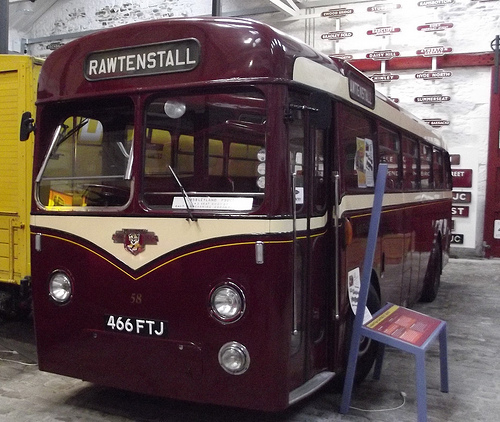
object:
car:
[18, 15, 446, 415]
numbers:
[102, 312, 170, 339]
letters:
[85, 47, 198, 76]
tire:
[429, 236, 449, 300]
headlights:
[212, 341, 255, 379]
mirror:
[19, 108, 33, 140]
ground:
[430, 144, 448, 189]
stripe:
[30, 188, 452, 270]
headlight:
[205, 278, 245, 327]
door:
[283, 89, 338, 391]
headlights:
[45, 268, 255, 378]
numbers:
[103, 312, 135, 333]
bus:
[32, 17, 486, 416]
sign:
[88, 46, 200, 75]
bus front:
[30, 13, 287, 405]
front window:
[139, 85, 269, 214]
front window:
[34, 93, 130, 210]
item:
[352, 298, 459, 404]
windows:
[429, 148, 449, 189]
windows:
[416, 141, 438, 191]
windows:
[400, 134, 421, 188]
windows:
[376, 130, 416, 191]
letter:
[154, 317, 166, 338]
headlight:
[46, 267, 73, 309]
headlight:
[205, 277, 250, 329]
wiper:
[164, 164, 194, 213]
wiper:
[31, 121, 61, 180]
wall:
[312, 0, 494, 255]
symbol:
[111, 227, 159, 257]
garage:
[0, 0, 490, 417]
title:
[87, 47, 196, 76]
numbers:
[105, 317, 135, 331]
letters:
[134, 318, 166, 337]